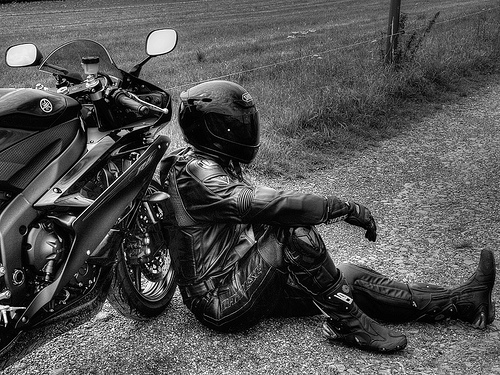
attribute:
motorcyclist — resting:
[136, 102, 440, 375]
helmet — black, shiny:
[162, 81, 269, 151]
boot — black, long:
[377, 254, 496, 333]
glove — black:
[333, 199, 384, 241]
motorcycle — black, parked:
[1, 35, 180, 340]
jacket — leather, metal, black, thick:
[156, 154, 300, 317]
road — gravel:
[373, 94, 494, 240]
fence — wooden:
[246, 1, 427, 71]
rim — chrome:
[124, 201, 165, 277]